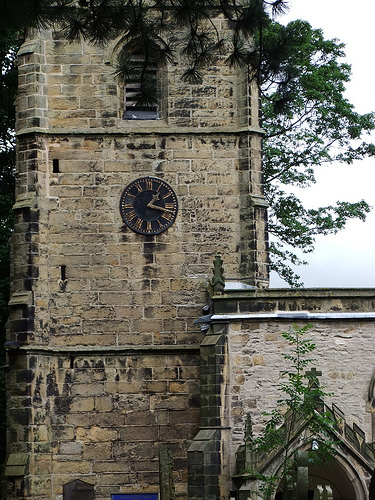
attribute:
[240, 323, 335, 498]
plant — is small, is thin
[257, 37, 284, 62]
branches — out, behind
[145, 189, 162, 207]
hour hand — clock's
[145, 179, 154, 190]
numeral — roman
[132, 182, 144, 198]
numeral — roman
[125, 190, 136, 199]
numeral — roman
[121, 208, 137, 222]
numeral — roman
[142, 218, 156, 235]
numeral — roman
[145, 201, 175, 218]
minute hand — clock's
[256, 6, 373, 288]
trees — behind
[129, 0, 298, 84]
tree — behind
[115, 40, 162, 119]
window — small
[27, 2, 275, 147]
branch — pine, tree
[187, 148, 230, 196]
bricks — black, gray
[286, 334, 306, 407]
tree — green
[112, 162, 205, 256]
clock — brown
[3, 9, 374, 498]
building — is large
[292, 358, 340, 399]
cross — small